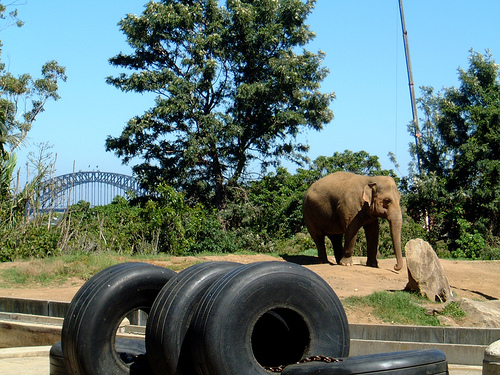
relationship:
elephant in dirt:
[301, 173, 402, 270] [1, 256, 496, 325]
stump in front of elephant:
[402, 237, 454, 303] [301, 173, 402, 270]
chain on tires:
[117, 350, 343, 370] [51, 260, 448, 373]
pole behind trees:
[397, 0, 430, 232] [398, 49, 498, 246]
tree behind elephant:
[102, 0, 333, 233] [301, 173, 402, 270]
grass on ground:
[0, 251, 468, 328] [0, 255, 499, 334]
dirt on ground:
[1, 256, 496, 325] [0, 255, 499, 334]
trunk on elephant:
[388, 209, 404, 273] [301, 173, 402, 270]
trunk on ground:
[388, 209, 404, 273] [0, 256, 498, 326]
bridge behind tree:
[9, 169, 177, 227] [0, 3, 71, 234]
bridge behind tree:
[9, 169, 177, 227] [102, 0, 333, 233]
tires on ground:
[60, 257, 183, 372] [4, 339, 498, 373]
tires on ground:
[142, 248, 255, 368] [4, 339, 498, 373]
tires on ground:
[193, 252, 357, 373] [4, 339, 498, 373]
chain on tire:
[293, 351, 345, 365] [184, 255, 361, 373]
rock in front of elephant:
[402, 234, 457, 307] [301, 169, 402, 272]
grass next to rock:
[348, 284, 443, 329] [399, 233, 454, 305]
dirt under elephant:
[0, 254, 500, 329] [301, 169, 402, 272]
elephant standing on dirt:
[301, 169, 402, 272] [0, 245, 499, 325]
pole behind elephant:
[395, 4, 433, 227] [301, 169, 402, 272]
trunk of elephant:
[386, 205, 407, 273] [301, 169, 402, 272]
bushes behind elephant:
[108, 152, 434, 262] [295, 164, 405, 274]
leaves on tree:
[103, 0, 336, 209] [102, 0, 333, 233]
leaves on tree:
[410, 49, 498, 239] [408, 49, 498, 238]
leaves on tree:
[350, 149, 381, 172] [294, 145, 402, 185]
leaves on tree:
[248, 163, 321, 238] [250, 165, 321, 233]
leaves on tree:
[119, 10, 165, 50] [102, 0, 333, 233]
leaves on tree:
[104, 46, 166, 68] [102, 0, 333, 233]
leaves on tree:
[104, 68, 174, 91] [102, 0, 333, 233]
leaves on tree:
[294, 46, 328, 87] [102, 0, 333, 233]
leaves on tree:
[301, 89, 335, 130] [102, 0, 333, 233]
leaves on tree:
[280, 0, 319, 49] [102, 0, 333, 233]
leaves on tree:
[458, 46, 498, 105] [408, 49, 498, 238]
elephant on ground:
[301, 169, 402, 272] [0, 256, 498, 326]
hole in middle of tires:
[247, 306, 310, 373] [193, 258, 352, 373]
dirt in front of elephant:
[0, 254, 500, 329] [301, 173, 402, 270]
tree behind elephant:
[251, 149, 381, 242] [301, 173, 402, 270]